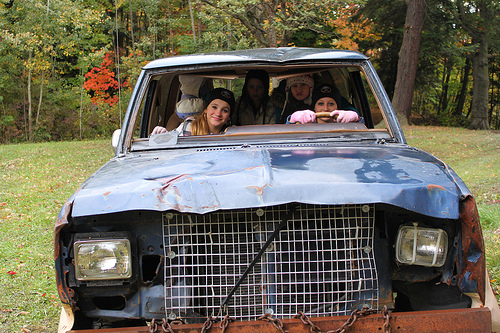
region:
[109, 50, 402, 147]
two person sitting in car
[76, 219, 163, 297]
head light of the car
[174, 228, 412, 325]
front part of the car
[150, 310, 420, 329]
a small iron chain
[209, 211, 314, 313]
a small black thread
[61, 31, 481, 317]
a beautiful old car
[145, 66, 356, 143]
group of people sitting in car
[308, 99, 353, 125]
steering of the car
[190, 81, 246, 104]
black cap wearing by girl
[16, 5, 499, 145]
a large group of trees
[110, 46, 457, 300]
old car is blue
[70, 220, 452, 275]
car has old headlights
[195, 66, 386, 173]
four people in car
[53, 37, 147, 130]
red tree behind car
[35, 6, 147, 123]
grove of trees behind car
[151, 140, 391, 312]
metal grille on car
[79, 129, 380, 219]
beat-up hood on blue car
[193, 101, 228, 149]
girl has brown hair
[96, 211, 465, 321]
car lacks grille cover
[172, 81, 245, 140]
girl is wearing cap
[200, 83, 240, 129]
the head of a woman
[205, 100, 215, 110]
the eye of a woman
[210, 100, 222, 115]
the nose of a woman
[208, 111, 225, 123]
the mouth of a woman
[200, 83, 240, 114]
a black hat on the woman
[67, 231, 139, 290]
a headlight on the car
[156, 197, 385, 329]
a grill on the car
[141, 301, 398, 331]
a chain on the car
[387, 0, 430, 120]
the trunk of a tree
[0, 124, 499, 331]
a green grassy field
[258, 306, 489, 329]
the bumper is rusted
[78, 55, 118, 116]
the leaves are red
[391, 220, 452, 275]
zipties are on the headlight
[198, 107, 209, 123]
the girl is wearing and earring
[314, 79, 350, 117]
the girl is wearing a cap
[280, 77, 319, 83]
the cap is white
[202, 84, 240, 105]
the cap is black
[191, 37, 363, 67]
the roof is dented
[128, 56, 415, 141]
the windshield is out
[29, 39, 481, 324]
the people are in the car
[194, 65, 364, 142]
people sitting in car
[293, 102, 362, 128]
two hands on steering wheel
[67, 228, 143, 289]
square headlight of car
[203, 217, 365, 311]
exposed grill of car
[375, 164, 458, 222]
bent edge of car hood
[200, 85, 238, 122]
girl in black hat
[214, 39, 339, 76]
dented roof of car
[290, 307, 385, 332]
chains on rusted bumper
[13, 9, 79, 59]
green leaves on tree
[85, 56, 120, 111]
red leaves on tree